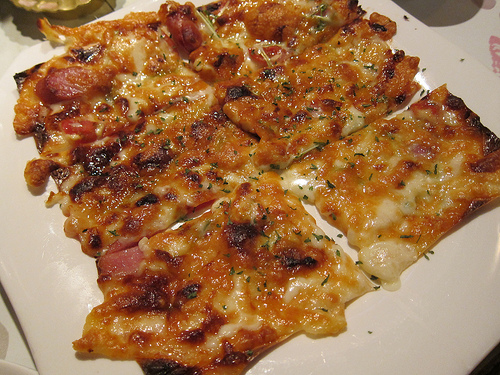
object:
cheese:
[31, 1, 500, 374]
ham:
[38, 48, 123, 109]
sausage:
[243, 32, 287, 78]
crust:
[0, 0, 500, 375]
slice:
[78, 170, 380, 375]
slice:
[276, 80, 500, 296]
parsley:
[148, 53, 360, 292]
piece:
[12, 20, 272, 255]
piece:
[156, 0, 416, 166]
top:
[14, 0, 500, 375]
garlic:
[190, 6, 264, 76]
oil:
[113, 59, 198, 120]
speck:
[360, 315, 385, 344]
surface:
[438, 269, 480, 343]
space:
[105, 117, 261, 254]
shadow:
[396, 0, 495, 35]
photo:
[8, 1, 500, 370]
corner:
[409, 48, 471, 165]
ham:
[89, 245, 153, 279]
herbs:
[316, 166, 337, 203]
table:
[8, 2, 497, 371]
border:
[5, 52, 76, 188]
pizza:
[6, 2, 499, 367]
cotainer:
[9, 0, 97, 15]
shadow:
[8, 0, 122, 43]